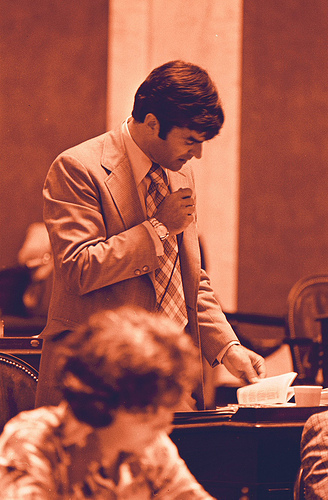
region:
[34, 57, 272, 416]
Man is wearing a suit and tie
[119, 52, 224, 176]
The man has brown hair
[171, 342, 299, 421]
A hand is turning a page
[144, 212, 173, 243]
A watch around a wrist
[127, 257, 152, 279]
Two buttons on jacket sleeve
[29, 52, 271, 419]
The man is standing up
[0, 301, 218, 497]
A person is sitting down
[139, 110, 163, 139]
An ear on man's head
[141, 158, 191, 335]
A tie around the man's neck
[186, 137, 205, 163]
Nose on man's face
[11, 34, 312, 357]
A man wearing a suit and tie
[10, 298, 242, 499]
A woman looking down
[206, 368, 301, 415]
A book on a desk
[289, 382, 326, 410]
A white Styrofoam coffee cup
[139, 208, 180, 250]
A watch on a man's wrist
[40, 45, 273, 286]
A man speaking into a microphone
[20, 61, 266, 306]
A man with dark hair wearing a tie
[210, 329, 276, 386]
A man's left hand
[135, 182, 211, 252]
A man's right hand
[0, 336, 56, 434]
The back of a chair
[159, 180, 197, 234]
a microphone in the man's hand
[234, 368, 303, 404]
the man flips through a book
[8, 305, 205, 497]
a woman looking down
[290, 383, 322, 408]
a drink on the table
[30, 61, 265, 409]
a man speaking from notes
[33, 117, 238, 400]
a suit from the 1970's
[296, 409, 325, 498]
another person sits out of frame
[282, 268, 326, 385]
an empty chair in the room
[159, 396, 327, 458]
a table holds the man's things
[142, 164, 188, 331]
a really hip tie on the man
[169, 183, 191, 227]
man is talking into a microphone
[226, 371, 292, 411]
man is holding the pages of a book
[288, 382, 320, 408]
cup on the desk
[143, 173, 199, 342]
man is wearing a plaid tie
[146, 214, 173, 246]
man is wearing a watch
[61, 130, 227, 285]
man is wearing a suit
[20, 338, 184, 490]
person is looking down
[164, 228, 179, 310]
cord for the microphone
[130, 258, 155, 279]
buttons on the sleeve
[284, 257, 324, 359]
empty chair at a table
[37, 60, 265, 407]
man in a suit standing up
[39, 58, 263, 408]
man talking into a microphone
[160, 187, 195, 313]
a microphone in the man's hand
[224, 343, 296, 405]
the man's left hand on a book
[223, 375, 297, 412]
a booklet on a desk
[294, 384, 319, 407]
a small white cup on the desk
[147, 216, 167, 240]
a silver wristwatch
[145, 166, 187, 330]
the man's plaid tie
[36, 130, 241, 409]
the man's tan suit jacket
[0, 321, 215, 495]
the woman sitting in front of the man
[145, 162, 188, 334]
plaid tie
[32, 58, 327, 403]
man speaking into microphone cupped in his hand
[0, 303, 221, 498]
blurry person reading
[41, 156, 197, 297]
man's right arm with cord coming out of fist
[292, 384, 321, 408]
cup on desk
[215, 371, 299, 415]
book with pages being turned